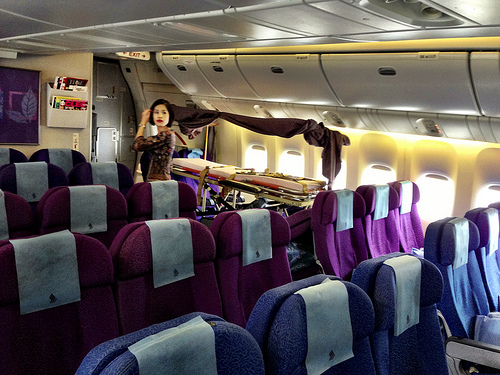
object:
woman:
[131, 98, 175, 182]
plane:
[0, 0, 500, 375]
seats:
[393, 179, 425, 253]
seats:
[376, 255, 450, 375]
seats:
[28, 148, 88, 176]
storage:
[156, 35, 500, 117]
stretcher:
[172, 158, 315, 194]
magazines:
[53, 75, 89, 92]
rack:
[46, 81, 88, 129]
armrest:
[445, 335, 500, 375]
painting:
[0, 66, 42, 146]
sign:
[115, 51, 150, 60]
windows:
[244, 144, 267, 173]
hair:
[149, 99, 176, 128]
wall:
[0, 51, 94, 164]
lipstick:
[156, 119, 163, 123]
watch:
[138, 124, 146, 128]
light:
[421, 6, 444, 20]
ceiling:
[0, 0, 499, 55]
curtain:
[166, 103, 352, 180]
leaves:
[21, 85, 38, 124]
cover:
[294, 277, 354, 375]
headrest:
[266, 280, 378, 375]